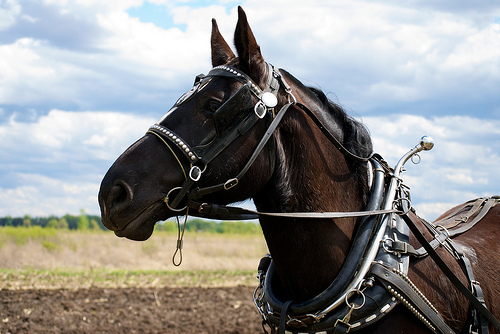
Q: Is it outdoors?
A: Yes, it is outdoors.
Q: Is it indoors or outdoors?
A: It is outdoors.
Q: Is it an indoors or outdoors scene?
A: It is outdoors.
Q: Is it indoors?
A: No, it is outdoors.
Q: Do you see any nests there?
A: No, there are no nests.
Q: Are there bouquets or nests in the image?
A: No, there are no nests or bouquets.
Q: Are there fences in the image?
A: No, there are no fences.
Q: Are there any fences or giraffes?
A: No, there are no fences or giraffes.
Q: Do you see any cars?
A: No, there are no cars.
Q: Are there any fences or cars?
A: No, there are no cars or fences.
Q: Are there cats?
A: No, there are no cats.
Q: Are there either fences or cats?
A: No, there are no cats or fences.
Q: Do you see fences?
A: No, there are no fences.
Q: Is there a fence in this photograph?
A: No, there are no fences.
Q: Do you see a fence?
A: No, there are no fences.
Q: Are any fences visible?
A: No, there are no fences.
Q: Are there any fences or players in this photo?
A: No, there are no fences or players.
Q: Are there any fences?
A: No, there are no fences.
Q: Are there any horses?
A: Yes, there is a horse.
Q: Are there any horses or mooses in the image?
A: Yes, there is a horse.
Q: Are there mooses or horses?
A: Yes, there is a horse.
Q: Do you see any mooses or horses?
A: Yes, there is a horse.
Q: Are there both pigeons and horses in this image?
A: No, there is a horse but no pigeons.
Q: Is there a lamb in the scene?
A: No, there are no lambs.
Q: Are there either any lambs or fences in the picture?
A: No, there are no lambs or fences.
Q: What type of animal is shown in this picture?
A: The animal is a horse.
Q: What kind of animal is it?
A: The animal is a horse.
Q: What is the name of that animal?
A: This is a horse.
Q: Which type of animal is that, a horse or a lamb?
A: This is a horse.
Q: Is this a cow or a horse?
A: This is a horse.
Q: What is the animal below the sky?
A: The animal is a horse.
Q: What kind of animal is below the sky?
A: The animal is a horse.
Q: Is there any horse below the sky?
A: Yes, there is a horse below the sky.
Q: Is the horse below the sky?
A: Yes, the horse is below the sky.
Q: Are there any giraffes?
A: No, there are no giraffes.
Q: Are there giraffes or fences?
A: No, there are no giraffes or fences.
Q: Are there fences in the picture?
A: No, there are no fences.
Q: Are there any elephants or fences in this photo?
A: No, there are no fences or elephants.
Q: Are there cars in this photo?
A: No, there are no cars.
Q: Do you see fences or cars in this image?
A: No, there are no cars or fences.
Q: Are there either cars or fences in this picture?
A: No, there are no cars or fences.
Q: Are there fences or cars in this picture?
A: No, there are no cars or fences.